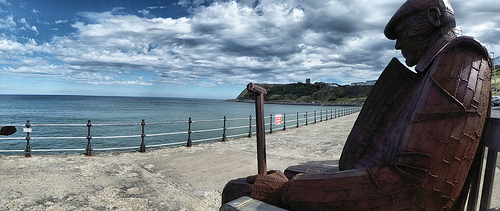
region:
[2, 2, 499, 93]
white clouds in sky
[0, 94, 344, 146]
surface of calm water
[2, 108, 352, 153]
poles on walkway railing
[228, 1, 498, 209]
side of seated statue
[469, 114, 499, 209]
back of bench behind statue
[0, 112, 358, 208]
concrete surface of walkway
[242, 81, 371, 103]
jetty hill overlooking water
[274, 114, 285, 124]
sign on fence rail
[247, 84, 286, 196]
cane in statue hand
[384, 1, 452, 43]
cap on statue head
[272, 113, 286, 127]
Red and white warning sign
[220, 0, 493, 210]
Brown statue of old man sitting on bench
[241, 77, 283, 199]
Brown walking cane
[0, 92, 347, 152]
large body of water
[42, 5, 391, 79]
Puffy white cirrus clouds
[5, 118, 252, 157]
protective gate surrounding the water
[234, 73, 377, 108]
rock water shore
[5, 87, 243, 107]
Water horizon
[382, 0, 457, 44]
old man's hat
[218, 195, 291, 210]
Park bench arm rest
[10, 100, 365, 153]
railing along the boardwalk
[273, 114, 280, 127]
red and white sign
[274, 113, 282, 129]
sign affixed to the railing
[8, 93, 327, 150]
water in front of boardwalk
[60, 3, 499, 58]
clouds gathering in the sky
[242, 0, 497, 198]
bronze statute of a man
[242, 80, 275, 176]
bronze cane that's part of the statute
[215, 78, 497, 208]
bench bronze statute is on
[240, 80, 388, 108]
cliff along the shoreline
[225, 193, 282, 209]
armrest on the bench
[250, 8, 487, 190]
brown metal sculpture of a man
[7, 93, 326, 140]
large body of water past a fence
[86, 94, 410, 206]
sandy beach area in front of fence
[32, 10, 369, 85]
blue sky with white fluffy clouds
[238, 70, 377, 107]
land formation with trees jutting out into the water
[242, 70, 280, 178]
walking stick of the metal man sculpture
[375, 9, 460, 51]
man sculpture's head and hat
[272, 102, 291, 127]
red and white sign on fence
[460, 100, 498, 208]
back of bench sculpture is sitting on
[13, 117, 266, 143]
fence line separating water from land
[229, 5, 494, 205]
brown statue of man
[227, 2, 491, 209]
statue of man on a chair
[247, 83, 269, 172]
walking cane in the man's left hand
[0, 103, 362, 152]
long railing along water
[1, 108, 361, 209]
walkway along the waterfront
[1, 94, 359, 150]
calm blue ocean waters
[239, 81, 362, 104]
green hilly shoreline with a cliff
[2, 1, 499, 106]
mostly cloudy skies above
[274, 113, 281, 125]
red sign on the railing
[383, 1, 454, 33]
golf cap on the statue